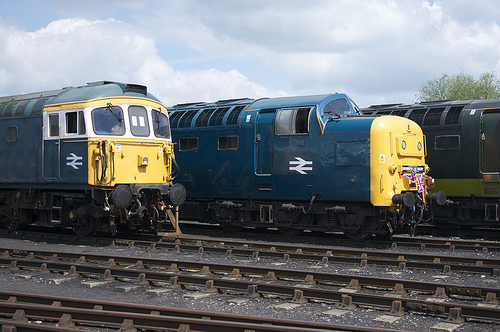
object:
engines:
[321, 114, 428, 207]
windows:
[422, 107, 447, 127]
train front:
[40, 80, 187, 237]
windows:
[128, 105, 151, 138]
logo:
[288, 156, 313, 174]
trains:
[357, 98, 500, 230]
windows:
[194, 108, 218, 128]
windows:
[226, 106, 247, 126]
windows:
[444, 106, 466, 126]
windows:
[30, 97, 50, 113]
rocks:
[270, 262, 287, 265]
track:
[0, 320, 95, 331]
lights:
[418, 142, 422, 150]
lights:
[402, 141, 406, 149]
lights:
[143, 157, 148, 164]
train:
[0, 80, 187, 238]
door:
[478, 108, 500, 175]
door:
[253, 108, 277, 177]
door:
[41, 104, 61, 182]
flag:
[415, 174, 425, 194]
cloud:
[0, 14, 292, 108]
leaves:
[415, 94, 417, 96]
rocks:
[226, 297, 251, 305]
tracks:
[0, 290, 414, 332]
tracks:
[1, 247, 500, 324]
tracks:
[0, 224, 500, 276]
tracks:
[162, 222, 500, 253]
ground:
[2, 220, 499, 332]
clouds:
[113, 0, 500, 110]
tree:
[409, 69, 500, 105]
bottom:
[160, 197, 375, 247]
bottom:
[0, 188, 112, 237]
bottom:
[424, 197, 500, 230]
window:
[275, 105, 316, 136]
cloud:
[0, 18, 294, 109]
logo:
[66, 153, 83, 170]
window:
[91, 105, 127, 136]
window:
[65, 111, 78, 135]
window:
[47, 113, 60, 138]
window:
[217, 135, 240, 151]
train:
[164, 91, 446, 241]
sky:
[0, 0, 500, 110]